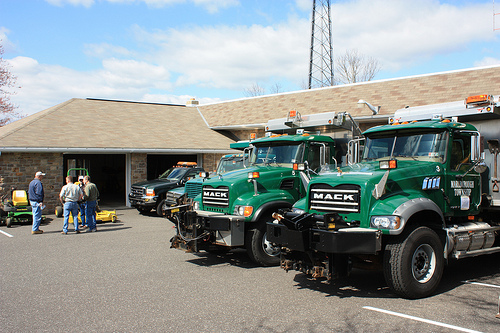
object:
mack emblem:
[203, 188, 229, 205]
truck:
[266, 93, 498, 298]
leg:
[190, 110, 389, 267]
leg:
[128, 160, 205, 216]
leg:
[163, 204, 192, 217]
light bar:
[177, 162, 197, 167]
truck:
[130, 162, 206, 216]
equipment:
[0, 189, 46, 228]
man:
[82, 176, 100, 232]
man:
[60, 176, 84, 235]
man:
[78, 175, 89, 228]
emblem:
[309, 183, 360, 213]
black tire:
[380, 225, 445, 298]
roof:
[0, 98, 246, 154]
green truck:
[162, 110, 372, 267]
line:
[360, 305, 485, 332]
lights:
[370, 215, 400, 230]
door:
[61, 153, 128, 208]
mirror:
[471, 135, 481, 161]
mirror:
[347, 140, 357, 165]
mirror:
[320, 146, 327, 165]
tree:
[332, 47, 380, 84]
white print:
[451, 180, 474, 195]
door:
[444, 130, 481, 213]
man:
[28, 171, 46, 235]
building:
[2, 65, 498, 219]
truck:
[181, 140, 279, 238]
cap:
[35, 171, 45, 176]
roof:
[204, 64, 499, 128]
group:
[30, 170, 100, 235]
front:
[129, 181, 156, 207]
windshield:
[364, 132, 442, 159]